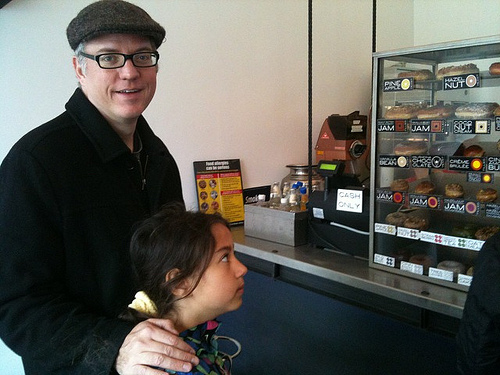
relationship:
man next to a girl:
[1, 1, 202, 374] [128, 211, 246, 374]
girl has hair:
[128, 211, 246, 374] [115, 212, 229, 327]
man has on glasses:
[1, 1, 202, 374] [79, 49, 159, 69]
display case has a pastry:
[378, 43, 500, 289] [461, 144, 484, 156]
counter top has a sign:
[225, 225, 467, 318] [194, 160, 247, 226]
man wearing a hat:
[1, 1, 202, 374] [67, 3, 166, 51]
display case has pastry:
[378, 43, 500, 289] [461, 144, 484, 156]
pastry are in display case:
[461, 144, 484, 156] [378, 43, 500, 289]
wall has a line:
[1, 0, 500, 375] [308, 1, 312, 164]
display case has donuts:
[378, 43, 500, 289] [446, 182, 465, 197]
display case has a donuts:
[378, 43, 500, 289] [446, 182, 465, 197]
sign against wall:
[194, 160, 247, 226] [1, 0, 500, 375]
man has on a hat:
[1, 1, 202, 374] [67, 3, 166, 51]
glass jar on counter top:
[283, 164, 324, 212] [225, 225, 467, 318]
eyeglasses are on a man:
[80, 47, 160, 67] [1, 1, 202, 374]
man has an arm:
[1, 1, 202, 374] [1, 146, 131, 371]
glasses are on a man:
[79, 49, 159, 69] [1, 1, 202, 374]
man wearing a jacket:
[1, 1, 202, 374] [1, 88, 187, 374]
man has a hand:
[1, 1, 202, 374] [114, 317, 200, 374]